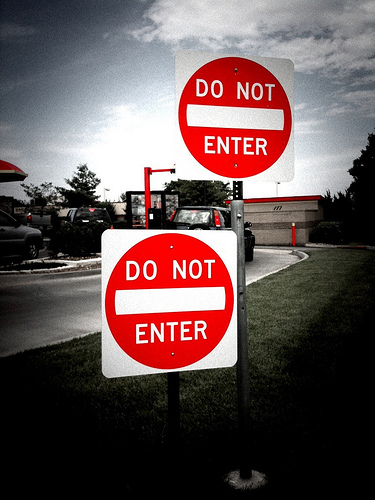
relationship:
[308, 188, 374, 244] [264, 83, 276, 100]
shrubs has letter t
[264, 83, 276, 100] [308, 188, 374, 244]
letter t on shrubs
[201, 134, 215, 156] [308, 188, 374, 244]
letter e on shrubs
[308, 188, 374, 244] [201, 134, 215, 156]
shrubs has letter e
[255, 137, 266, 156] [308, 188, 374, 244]
letter r on shrubs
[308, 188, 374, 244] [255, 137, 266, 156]
shrubs has letter r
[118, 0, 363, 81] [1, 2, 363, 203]
cloud hanging in sky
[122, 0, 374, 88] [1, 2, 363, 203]
cloud hanging in sky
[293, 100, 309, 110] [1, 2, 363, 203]
cloud hanging in sky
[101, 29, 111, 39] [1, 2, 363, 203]
cloud hanging in sky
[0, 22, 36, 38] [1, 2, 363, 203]
cloud hanging in sky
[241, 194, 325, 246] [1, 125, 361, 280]
building standing in background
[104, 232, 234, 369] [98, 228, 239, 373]
circle on sign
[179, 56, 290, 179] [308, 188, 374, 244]
circle on shrubs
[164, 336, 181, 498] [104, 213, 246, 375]
sign post attached to sign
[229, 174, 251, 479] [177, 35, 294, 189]
pole attached to sign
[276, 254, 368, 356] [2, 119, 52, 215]
grass next to restaurant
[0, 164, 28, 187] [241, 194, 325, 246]
umbrella near building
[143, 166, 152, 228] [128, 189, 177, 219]
pole next to drive through menu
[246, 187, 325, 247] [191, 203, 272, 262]
building next to drivethru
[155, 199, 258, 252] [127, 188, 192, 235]
car pulled up to order board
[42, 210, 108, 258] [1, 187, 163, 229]
car in line at drivethru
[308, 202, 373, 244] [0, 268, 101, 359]
shrubs separating pavement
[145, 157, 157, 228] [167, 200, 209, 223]
pole with height accessible to window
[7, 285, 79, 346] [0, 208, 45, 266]
pavement of drive through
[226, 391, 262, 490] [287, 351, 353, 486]
pole cemented in ground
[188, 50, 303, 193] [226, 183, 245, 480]
sign on a pole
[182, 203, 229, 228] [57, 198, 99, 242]
windows of  a car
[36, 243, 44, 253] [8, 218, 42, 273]
wheel of  a car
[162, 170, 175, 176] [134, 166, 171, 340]
light on a pole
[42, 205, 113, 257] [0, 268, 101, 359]
car on a pavement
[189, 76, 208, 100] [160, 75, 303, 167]
letter on sign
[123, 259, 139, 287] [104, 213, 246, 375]
letter on sign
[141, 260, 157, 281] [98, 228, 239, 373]
letter on sign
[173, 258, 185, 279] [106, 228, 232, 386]
letter on sign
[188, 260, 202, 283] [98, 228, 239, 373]
letter on sign